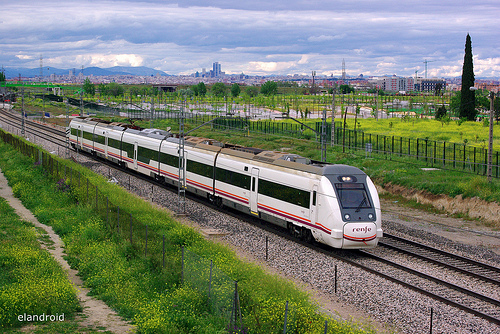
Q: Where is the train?
A: On the tracks.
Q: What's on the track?
A: Train.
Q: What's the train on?
A: Track.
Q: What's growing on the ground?
A: Grass.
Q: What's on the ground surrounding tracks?
A: Rocks.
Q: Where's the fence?
A: In grass.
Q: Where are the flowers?
A: In grass.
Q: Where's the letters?
A: Front of train.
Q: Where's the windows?
A: On train.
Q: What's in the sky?
A: Clouds.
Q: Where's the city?
A: In the horizon.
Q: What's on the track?
A: Train.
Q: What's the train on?
A: Track.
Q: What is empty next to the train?
A: Track.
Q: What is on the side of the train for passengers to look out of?
A: Windows.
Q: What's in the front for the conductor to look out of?
A: Windshield.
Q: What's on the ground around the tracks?
A: Rocks.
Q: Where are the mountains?
A: Beyond the city.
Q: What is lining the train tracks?
A: Fence.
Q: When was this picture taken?
A: Day time.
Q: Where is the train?
A: On the tracks.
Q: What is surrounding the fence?
A: Grass.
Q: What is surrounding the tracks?
A: Gravel.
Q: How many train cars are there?
A: Five.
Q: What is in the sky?
A: Clouds.